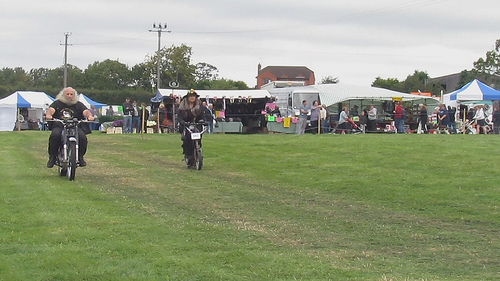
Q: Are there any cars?
A: No, there are no cars.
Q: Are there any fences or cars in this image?
A: No, there are no cars or fences.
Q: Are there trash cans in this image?
A: No, there are no trash cans.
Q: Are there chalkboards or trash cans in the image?
A: No, there are no trash cans or chalkboards.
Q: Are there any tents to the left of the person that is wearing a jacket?
A: Yes, there is a tent to the left of the person.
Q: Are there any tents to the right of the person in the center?
A: No, the tent is to the left of the person.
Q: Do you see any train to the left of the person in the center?
A: No, there is a tent to the left of the person.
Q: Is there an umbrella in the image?
A: Yes, there is an umbrella.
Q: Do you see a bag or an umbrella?
A: Yes, there is an umbrella.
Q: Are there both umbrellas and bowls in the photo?
A: No, there is an umbrella but no bowls.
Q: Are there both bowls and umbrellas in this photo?
A: No, there is an umbrella but no bowls.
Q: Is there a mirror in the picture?
A: No, there are no mirrors.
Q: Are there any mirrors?
A: No, there are no mirrors.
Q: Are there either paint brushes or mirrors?
A: No, there are no mirrors or paint brushes.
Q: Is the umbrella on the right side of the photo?
A: Yes, the umbrella is on the right of the image.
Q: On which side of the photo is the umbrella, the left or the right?
A: The umbrella is on the right of the image.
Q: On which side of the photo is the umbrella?
A: The umbrella is on the right of the image.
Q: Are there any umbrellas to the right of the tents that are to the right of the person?
A: Yes, there is an umbrella to the right of the tents.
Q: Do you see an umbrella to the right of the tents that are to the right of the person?
A: Yes, there is an umbrella to the right of the tents.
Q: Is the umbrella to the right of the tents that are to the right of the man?
A: Yes, the umbrella is to the right of the tents.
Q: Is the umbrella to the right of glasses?
A: No, the umbrella is to the right of the tents.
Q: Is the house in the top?
A: Yes, the house is in the top of the image.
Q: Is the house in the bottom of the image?
A: No, the house is in the top of the image.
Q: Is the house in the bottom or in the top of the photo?
A: The house is in the top of the image.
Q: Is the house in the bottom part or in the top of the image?
A: The house is in the top of the image.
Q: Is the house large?
A: Yes, the house is large.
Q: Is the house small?
A: No, the house is large.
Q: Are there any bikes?
A: Yes, there is a bike.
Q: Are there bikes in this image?
A: Yes, there is a bike.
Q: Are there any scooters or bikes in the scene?
A: Yes, there is a bike.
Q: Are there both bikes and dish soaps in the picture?
A: No, there is a bike but no dish soaps.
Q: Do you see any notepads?
A: No, there are no notepads.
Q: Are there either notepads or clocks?
A: No, there are no notepads or clocks.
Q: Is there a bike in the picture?
A: Yes, there is a bike.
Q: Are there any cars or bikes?
A: Yes, there is a bike.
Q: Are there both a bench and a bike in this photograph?
A: No, there is a bike but no benches.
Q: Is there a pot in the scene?
A: No, there are no pots.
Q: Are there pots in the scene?
A: No, there are no pots.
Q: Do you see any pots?
A: No, there are no pots.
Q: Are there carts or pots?
A: No, there are no pots or carts.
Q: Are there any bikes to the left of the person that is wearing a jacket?
A: Yes, there is a bike to the left of the person.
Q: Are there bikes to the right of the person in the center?
A: No, the bike is to the left of the person.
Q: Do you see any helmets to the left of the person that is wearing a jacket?
A: No, there is a bike to the left of the person.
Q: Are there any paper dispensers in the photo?
A: No, there are no paper dispensers.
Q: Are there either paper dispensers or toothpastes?
A: No, there are no paper dispensers or toothpastes.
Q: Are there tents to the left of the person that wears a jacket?
A: Yes, there is a tent to the left of the person.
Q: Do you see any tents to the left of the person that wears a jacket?
A: Yes, there is a tent to the left of the person.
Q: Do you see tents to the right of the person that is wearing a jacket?
A: No, the tent is to the left of the person.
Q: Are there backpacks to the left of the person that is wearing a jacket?
A: No, there is a tent to the left of the person.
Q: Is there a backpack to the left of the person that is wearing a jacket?
A: No, there is a tent to the left of the person.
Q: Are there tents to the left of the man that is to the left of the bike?
A: Yes, there is a tent to the left of the man.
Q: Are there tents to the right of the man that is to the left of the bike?
A: No, the tent is to the left of the man.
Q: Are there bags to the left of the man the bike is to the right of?
A: No, there is a tent to the left of the man.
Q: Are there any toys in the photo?
A: No, there are no toys.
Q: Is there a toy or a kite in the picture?
A: No, there are no toys or kites.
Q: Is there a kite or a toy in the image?
A: No, there are no toys or kites.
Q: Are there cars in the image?
A: No, there are no cars.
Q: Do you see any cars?
A: No, there are no cars.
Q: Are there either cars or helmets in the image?
A: No, there are no cars or helmets.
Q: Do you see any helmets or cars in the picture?
A: No, there are no cars or helmets.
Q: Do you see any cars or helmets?
A: No, there are no cars or helmets.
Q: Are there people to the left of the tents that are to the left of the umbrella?
A: Yes, there is a person to the left of the tents.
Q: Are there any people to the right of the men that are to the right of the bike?
A: Yes, there is a person to the right of the men.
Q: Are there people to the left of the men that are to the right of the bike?
A: No, the person is to the right of the men.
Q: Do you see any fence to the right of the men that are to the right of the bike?
A: No, there is a person to the right of the men.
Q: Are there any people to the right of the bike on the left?
A: Yes, there is a person to the right of the bike.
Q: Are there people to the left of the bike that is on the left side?
A: No, the person is to the right of the bike.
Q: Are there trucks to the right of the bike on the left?
A: No, there is a person to the right of the bike.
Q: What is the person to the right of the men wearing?
A: The person is wearing a jacket.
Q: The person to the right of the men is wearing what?
A: The person is wearing a jacket.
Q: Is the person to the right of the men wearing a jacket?
A: Yes, the person is wearing a jacket.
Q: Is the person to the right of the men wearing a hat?
A: No, the person is wearing a jacket.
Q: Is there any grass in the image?
A: Yes, there is grass.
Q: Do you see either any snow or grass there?
A: Yes, there is grass.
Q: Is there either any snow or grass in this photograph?
A: Yes, there is grass.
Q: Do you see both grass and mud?
A: No, there is grass but no mud.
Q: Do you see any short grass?
A: Yes, there is short grass.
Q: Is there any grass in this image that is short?
A: Yes, there is grass that is short.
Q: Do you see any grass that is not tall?
A: Yes, there is short grass.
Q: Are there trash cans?
A: No, there are no trash cans.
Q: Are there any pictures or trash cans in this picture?
A: No, there are no trash cans or pictures.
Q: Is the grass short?
A: Yes, the grass is short.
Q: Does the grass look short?
A: Yes, the grass is short.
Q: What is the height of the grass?
A: The grass is short.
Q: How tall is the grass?
A: The grass is short.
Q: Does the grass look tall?
A: No, the grass is short.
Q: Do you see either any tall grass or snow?
A: No, there is grass but it is short.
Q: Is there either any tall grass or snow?
A: No, there is grass but it is short.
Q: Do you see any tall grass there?
A: No, there is grass but it is short.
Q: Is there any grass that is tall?
A: No, there is grass but it is short.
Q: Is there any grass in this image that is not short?
A: No, there is grass but it is short.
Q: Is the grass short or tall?
A: The grass is short.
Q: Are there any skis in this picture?
A: No, there are no skis.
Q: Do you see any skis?
A: No, there are no skis.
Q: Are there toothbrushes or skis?
A: No, there are no skis or toothbrushes.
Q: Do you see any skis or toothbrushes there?
A: No, there are no skis or toothbrushes.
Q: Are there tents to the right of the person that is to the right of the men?
A: Yes, there are tents to the right of the person.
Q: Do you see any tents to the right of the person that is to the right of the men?
A: Yes, there are tents to the right of the person.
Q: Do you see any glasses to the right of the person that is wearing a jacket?
A: No, there are tents to the right of the person.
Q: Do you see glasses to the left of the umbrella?
A: No, there are tents to the left of the umbrella.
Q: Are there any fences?
A: No, there are no fences.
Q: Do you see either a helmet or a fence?
A: No, there are no fences or helmets.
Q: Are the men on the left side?
A: Yes, the men are on the left of the image.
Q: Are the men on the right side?
A: No, the men are on the left of the image.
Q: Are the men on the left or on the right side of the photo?
A: The men are on the left of the image.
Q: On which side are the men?
A: The men are on the left of the image.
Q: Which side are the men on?
A: The men are on the left of the image.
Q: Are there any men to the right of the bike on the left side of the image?
A: Yes, there are men to the right of the bike.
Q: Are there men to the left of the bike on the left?
A: No, the men are to the right of the bike.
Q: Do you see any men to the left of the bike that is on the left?
A: No, the men are to the right of the bike.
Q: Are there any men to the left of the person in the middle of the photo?
A: Yes, there are men to the left of the person.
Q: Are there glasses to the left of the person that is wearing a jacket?
A: No, there are men to the left of the person.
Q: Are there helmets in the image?
A: No, there are no helmets.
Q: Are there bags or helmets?
A: No, there are no helmets or bags.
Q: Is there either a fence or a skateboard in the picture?
A: No, there are no fences or skateboards.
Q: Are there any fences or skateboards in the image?
A: No, there are no fences or skateboards.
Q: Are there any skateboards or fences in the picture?
A: No, there are no fences or skateboards.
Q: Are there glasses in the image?
A: No, there are no glasses.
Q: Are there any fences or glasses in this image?
A: No, there are no glasses or fences.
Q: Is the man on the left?
A: Yes, the man is on the left of the image.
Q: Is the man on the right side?
A: No, the man is on the left of the image.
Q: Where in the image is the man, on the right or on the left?
A: The man is on the left of the image.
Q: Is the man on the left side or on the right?
A: The man is on the left of the image.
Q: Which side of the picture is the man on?
A: The man is on the left of the image.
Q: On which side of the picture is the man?
A: The man is on the left of the image.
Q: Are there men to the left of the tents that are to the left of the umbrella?
A: Yes, there is a man to the left of the tents.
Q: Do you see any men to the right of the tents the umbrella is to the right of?
A: No, the man is to the left of the tents.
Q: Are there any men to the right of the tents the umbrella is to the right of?
A: No, the man is to the left of the tents.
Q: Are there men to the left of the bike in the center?
A: Yes, there is a man to the left of the bike.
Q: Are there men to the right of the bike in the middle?
A: No, the man is to the left of the bike.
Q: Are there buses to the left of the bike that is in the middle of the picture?
A: No, there is a man to the left of the bike.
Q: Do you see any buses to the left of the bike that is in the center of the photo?
A: No, there is a man to the left of the bike.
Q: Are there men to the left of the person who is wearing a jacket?
A: Yes, there is a man to the left of the person.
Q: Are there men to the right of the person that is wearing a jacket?
A: No, the man is to the left of the person.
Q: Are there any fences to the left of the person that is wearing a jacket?
A: No, there is a man to the left of the person.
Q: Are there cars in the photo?
A: No, there are no cars.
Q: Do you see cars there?
A: No, there are no cars.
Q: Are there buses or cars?
A: No, there are no cars or buses.